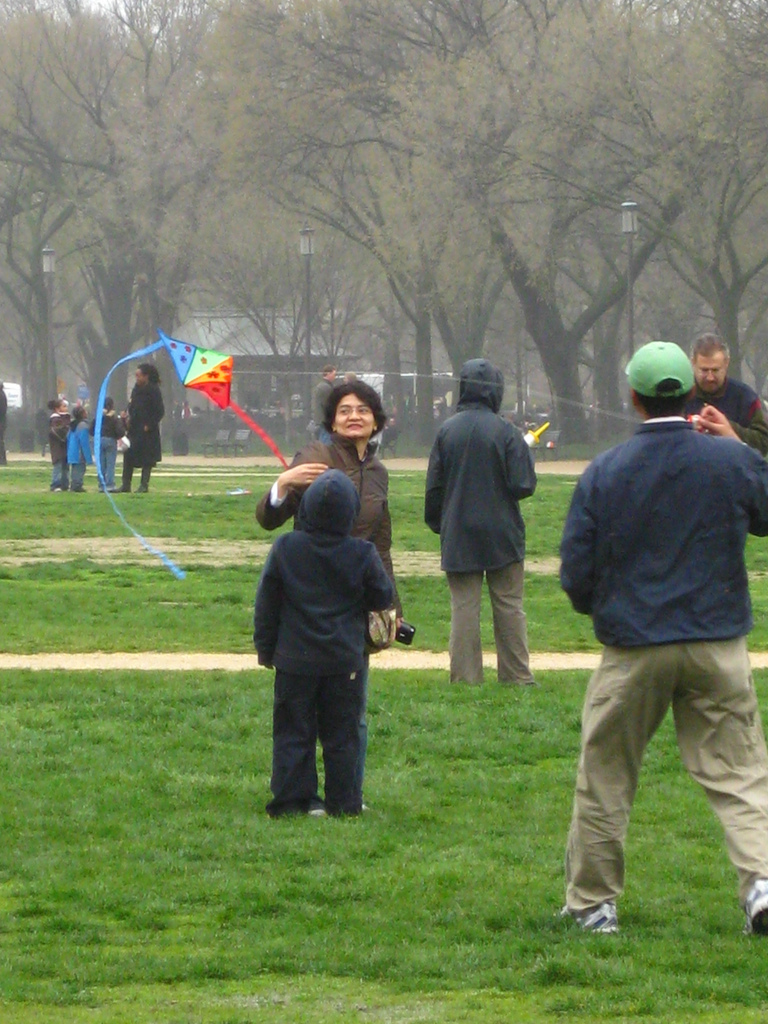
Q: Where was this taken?
A: At a park.